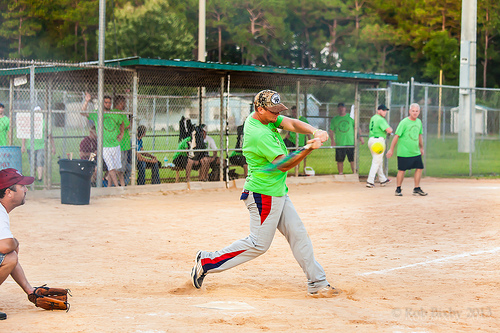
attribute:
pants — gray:
[181, 77, 349, 302]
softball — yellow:
[367, 139, 384, 154]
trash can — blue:
[57, 158, 97, 204]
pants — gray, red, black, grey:
[201, 190, 329, 292]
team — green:
[91, 95, 236, 175]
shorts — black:
[382, 143, 434, 172]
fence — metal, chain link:
[1, 57, 498, 186]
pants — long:
[201, 181, 330, 288]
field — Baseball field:
[0, 144, 498, 330]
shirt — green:
[241, 110, 290, 200]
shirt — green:
[83, 109, 134, 149]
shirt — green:
[328, 112, 358, 150]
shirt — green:
[366, 112, 390, 141]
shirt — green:
[391, 114, 426, 160]